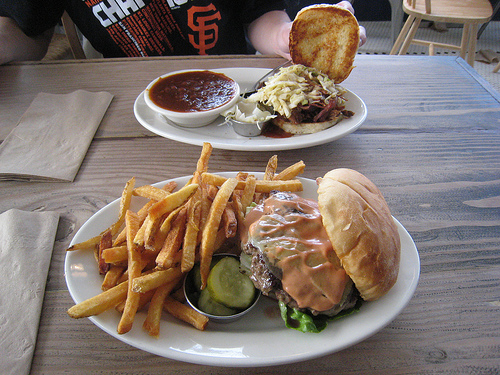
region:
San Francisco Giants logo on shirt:
[188, 3, 224, 51]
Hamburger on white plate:
[258, 171, 391, 313]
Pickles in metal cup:
[191, 261, 259, 322]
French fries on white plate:
[69, 166, 236, 249]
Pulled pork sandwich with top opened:
[270, 4, 356, 122]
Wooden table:
[387, 64, 487, 199]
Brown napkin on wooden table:
[0, 85, 116, 182]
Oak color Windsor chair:
[392, 0, 492, 55]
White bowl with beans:
[146, 67, 239, 110]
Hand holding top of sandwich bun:
[252, 0, 368, 63]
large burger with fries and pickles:
[110, 163, 407, 349]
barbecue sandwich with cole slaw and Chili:
[135, 27, 357, 152]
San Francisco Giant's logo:
[160, 5, 240, 60]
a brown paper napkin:
[20, 85, 115, 185]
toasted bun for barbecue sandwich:
[300, 10, 370, 80]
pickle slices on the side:
[152, 235, 282, 350]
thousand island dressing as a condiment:
[270, 206, 335, 311]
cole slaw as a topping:
[252, 61, 329, 106]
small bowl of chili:
[137, 57, 232, 133]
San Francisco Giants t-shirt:
[77, 6, 285, 63]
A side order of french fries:
[65, 136, 313, 351]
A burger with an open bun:
[225, 159, 407, 348]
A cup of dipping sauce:
[144, 60, 236, 131]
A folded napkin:
[0, 82, 128, 200]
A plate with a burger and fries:
[47, 150, 424, 365]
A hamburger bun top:
[310, 157, 410, 309]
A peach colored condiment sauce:
[230, 187, 345, 312]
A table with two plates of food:
[6, 39, 498, 368]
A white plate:
[129, 113, 362, 156]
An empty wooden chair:
[371, 0, 496, 60]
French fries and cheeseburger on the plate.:
[81, 198, 463, 366]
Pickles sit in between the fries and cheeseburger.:
[178, 216, 267, 326]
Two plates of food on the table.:
[91, 85, 398, 367]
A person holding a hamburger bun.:
[252, 20, 407, 100]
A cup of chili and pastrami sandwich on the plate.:
[142, 60, 357, 146]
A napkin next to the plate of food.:
[20, 80, 131, 172]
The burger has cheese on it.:
[270, 185, 390, 310]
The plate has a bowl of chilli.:
[136, 55, 381, 156]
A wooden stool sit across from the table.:
[398, 8, 484, 68]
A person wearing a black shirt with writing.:
[73, 5, 270, 53]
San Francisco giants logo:
[189, 6, 221, 51]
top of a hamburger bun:
[333, 168, 396, 288]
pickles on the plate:
[215, 260, 242, 308]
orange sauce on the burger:
[279, 203, 316, 280]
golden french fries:
[162, 181, 227, 239]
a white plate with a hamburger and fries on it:
[116, 177, 416, 327]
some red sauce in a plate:
[163, 65, 222, 119]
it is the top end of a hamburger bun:
[301, 12, 356, 64]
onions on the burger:
[281, 72, 308, 112]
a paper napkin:
[32, 83, 82, 185]